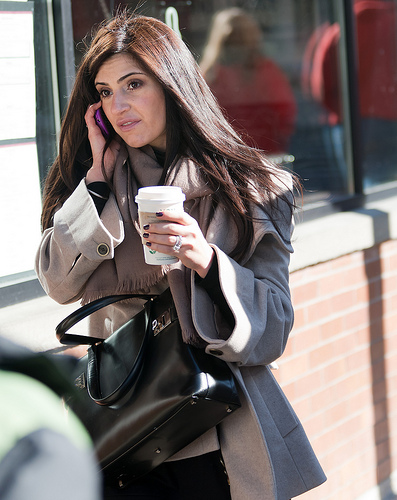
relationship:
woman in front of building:
[35, 14, 327, 500] [0, 0, 396, 499]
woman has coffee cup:
[35, 14, 327, 500] [133, 185, 184, 267]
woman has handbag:
[35, 14, 327, 500] [28, 286, 240, 495]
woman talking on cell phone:
[35, 14, 327, 500] [94, 106, 112, 139]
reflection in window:
[198, 10, 297, 156] [72, 4, 394, 223]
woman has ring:
[35, 14, 327, 500] [171, 234, 184, 255]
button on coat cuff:
[96, 244, 110, 256] [60, 177, 125, 261]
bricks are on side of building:
[306, 327, 367, 369] [0, 0, 396, 499]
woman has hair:
[35, 14, 327, 500] [41, 7, 303, 258]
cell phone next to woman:
[94, 106, 112, 139] [35, 14, 327, 500]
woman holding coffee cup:
[35, 14, 327, 500] [133, 185, 184, 267]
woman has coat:
[35, 14, 327, 500] [34, 151, 329, 498]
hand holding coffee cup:
[141, 210, 217, 280] [133, 185, 184, 267]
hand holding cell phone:
[141, 210, 217, 280] [94, 106, 112, 139]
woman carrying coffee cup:
[35, 14, 327, 500] [133, 185, 184, 267]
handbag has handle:
[28, 286, 240, 495] [54, 288, 160, 407]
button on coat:
[96, 244, 110, 256] [34, 151, 329, 498]